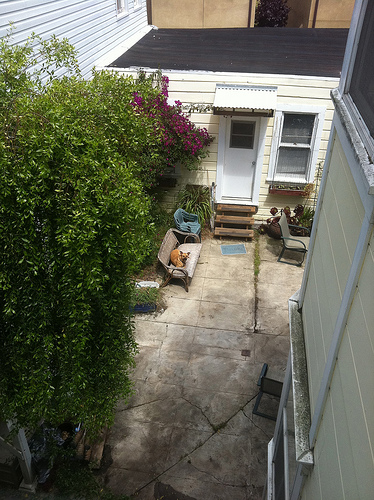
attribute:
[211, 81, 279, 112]
awning — small 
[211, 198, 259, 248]
steps — set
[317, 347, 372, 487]
wall — white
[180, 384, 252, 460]
floor — cracked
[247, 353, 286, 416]
chair — wooden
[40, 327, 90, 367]
tree — green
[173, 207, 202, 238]
arm chair — sky blue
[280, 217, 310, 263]
arm chair — empty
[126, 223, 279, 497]
ground surface — concrete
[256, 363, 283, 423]
chair — outdoor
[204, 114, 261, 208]
door — white